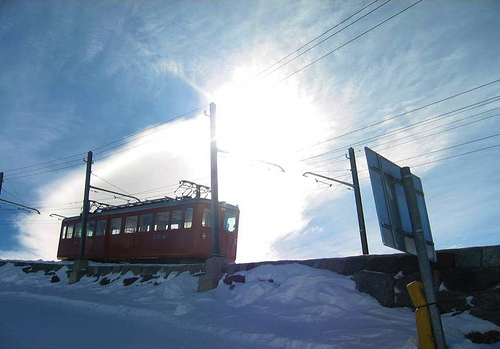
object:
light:
[300, 170, 336, 189]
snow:
[89, 260, 179, 267]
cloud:
[149, 77, 208, 122]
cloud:
[227, 5, 303, 43]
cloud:
[370, 57, 452, 97]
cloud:
[449, 176, 494, 219]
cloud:
[22, 52, 88, 109]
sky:
[0, 0, 500, 144]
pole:
[346, 145, 370, 254]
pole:
[77, 149, 93, 258]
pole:
[0, 170, 4, 191]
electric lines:
[0, 148, 88, 174]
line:
[235, 77, 500, 158]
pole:
[68, 148, 94, 282]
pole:
[201, 102, 224, 257]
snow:
[3, 263, 498, 347]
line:
[287, 95, 499, 165]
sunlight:
[213, 70, 371, 172]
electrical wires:
[399, 132, 500, 164]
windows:
[182, 207, 194, 230]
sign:
[365, 145, 447, 347]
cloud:
[14, 167, 317, 262]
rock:
[352, 269, 394, 307]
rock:
[223, 275, 246, 288]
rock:
[123, 277, 139, 286]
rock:
[48, 274, 59, 282]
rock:
[97, 277, 111, 285]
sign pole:
[396, 165, 448, 346]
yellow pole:
[406, 280, 434, 349]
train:
[53, 194, 242, 261]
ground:
[0, 256, 500, 349]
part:
[304, 295, 345, 328]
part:
[167, 223, 181, 250]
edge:
[415, 252, 426, 306]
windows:
[168, 206, 184, 232]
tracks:
[1, 249, 498, 292]